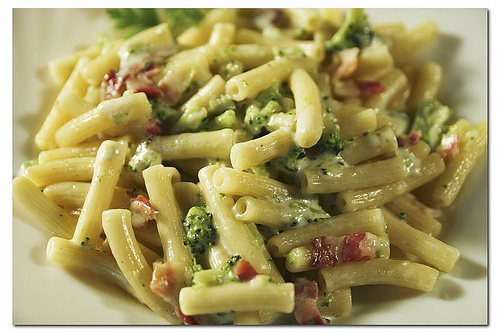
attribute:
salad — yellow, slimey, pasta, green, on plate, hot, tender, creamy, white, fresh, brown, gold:
[33, 13, 463, 313]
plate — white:
[39, 256, 458, 332]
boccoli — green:
[182, 206, 215, 245]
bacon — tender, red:
[116, 66, 169, 89]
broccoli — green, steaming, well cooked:
[166, 194, 219, 244]